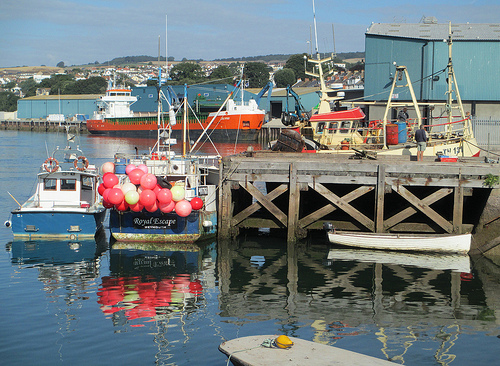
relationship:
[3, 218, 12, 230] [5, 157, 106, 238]
buoy hanging on boat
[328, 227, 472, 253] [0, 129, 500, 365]
boat in water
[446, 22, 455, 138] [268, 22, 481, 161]
mast on boat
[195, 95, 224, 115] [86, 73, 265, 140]
engine on boat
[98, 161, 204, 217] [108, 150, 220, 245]
balloons on boat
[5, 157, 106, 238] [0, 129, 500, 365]
boat in water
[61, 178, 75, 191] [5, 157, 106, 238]
window on boat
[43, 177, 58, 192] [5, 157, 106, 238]
window on boat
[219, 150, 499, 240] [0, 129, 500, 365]
pier on water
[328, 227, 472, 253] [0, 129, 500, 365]
canoe in water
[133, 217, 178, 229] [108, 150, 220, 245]
name on boat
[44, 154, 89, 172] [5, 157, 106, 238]
life preserver on boat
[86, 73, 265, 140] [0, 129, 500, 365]
boat in water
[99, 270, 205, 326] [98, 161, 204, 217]
reflection of balloons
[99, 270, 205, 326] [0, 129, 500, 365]
reflection in water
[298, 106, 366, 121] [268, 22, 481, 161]
roof on boat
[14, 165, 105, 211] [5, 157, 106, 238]
top of boat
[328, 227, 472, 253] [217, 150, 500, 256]
boat near pier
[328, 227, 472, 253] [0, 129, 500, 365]
canoe on water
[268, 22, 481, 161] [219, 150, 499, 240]
boat by pier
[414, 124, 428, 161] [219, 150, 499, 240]
man on pier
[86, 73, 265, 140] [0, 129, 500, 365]
boat on water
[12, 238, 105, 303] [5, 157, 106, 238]
reflection of boat